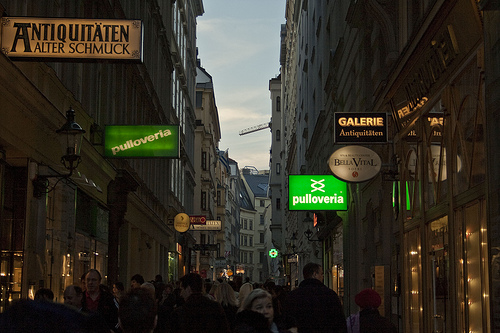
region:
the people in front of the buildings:
[0, 261, 393, 331]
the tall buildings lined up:
[0, 0, 498, 330]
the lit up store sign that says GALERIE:
[333, 110, 387, 142]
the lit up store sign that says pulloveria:
[288, 173, 345, 210]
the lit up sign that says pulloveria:
[103, 123, 179, 155]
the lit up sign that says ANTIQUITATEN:
[1, 18, 141, 60]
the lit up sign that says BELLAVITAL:
[327, 144, 382, 180]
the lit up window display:
[396, 201, 493, 331]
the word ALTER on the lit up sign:
[33, 41, 65, 53]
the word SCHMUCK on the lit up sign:
[66, 42, 129, 54]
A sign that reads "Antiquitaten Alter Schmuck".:
[0, 15, 146, 65]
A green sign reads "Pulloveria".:
[101, 121, 181, 158]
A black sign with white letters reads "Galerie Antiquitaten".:
[332, 113, 388, 144]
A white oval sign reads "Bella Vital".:
[327, 143, 384, 183]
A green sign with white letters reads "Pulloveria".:
[287, 173, 349, 212]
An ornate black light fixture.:
[30, 105, 88, 202]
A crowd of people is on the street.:
[0, 261, 393, 331]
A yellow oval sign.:
[172, 211, 191, 232]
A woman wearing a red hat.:
[344, 288, 394, 331]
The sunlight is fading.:
[192, 0, 284, 170]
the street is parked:
[76, 266, 341, 331]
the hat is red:
[352, 278, 381, 308]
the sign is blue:
[111, 121, 178, 156]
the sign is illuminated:
[293, 170, 347, 212]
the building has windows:
[231, 210, 269, 276]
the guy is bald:
[60, 280, 83, 307]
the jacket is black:
[285, 273, 356, 329]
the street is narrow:
[131, 225, 301, 317]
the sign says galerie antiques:
[340, 115, 386, 135]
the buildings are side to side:
[1, 59, 498, 260]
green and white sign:
[284, 176, 346, 213]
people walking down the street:
[39, 241, 374, 331]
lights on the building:
[455, 220, 495, 332]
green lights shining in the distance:
[266, 244, 278, 257]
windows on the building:
[239, 215, 256, 275]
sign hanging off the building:
[103, 116, 189, 159]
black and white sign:
[336, 111, 394, 143]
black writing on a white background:
[8, 16, 140, 61]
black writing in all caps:
[9, 18, 133, 59]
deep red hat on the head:
[354, 290, 384, 312]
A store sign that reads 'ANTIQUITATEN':
[1, 18, 146, 59]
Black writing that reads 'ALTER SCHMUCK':
[31, 37, 136, 62]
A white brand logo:
[306, 175, 331, 193]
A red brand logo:
[346, 167, 363, 183]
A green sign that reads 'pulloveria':
[100, 117, 189, 162]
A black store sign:
[330, 104, 393, 147]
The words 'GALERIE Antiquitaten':
[336, 110, 389, 138]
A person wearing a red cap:
[346, 280, 393, 331]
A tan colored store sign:
[169, 209, 193, 238]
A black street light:
[31, 103, 98, 205]